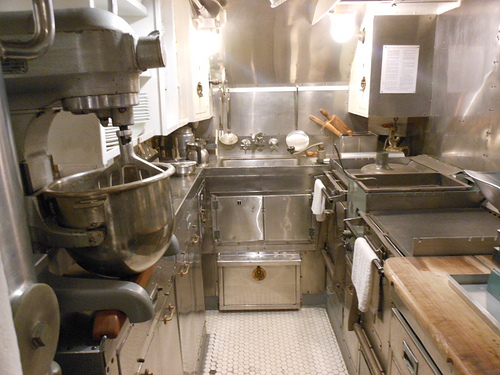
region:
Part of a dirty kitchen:
[197, 163, 332, 324]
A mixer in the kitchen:
[87, 135, 192, 253]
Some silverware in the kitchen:
[250, 104, 395, 179]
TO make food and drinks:
[69, 123, 218, 267]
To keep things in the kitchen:
[168, 158, 350, 253]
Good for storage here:
[166, 155, 361, 266]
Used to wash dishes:
[221, 133, 306, 181]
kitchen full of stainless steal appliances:
[2, 6, 498, 371]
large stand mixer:
[7, 12, 184, 280]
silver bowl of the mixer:
[51, 162, 174, 270]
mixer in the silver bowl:
[94, 124, 164, 190]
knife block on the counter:
[307, 111, 357, 150]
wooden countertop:
[380, 257, 494, 373]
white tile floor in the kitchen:
[198, 299, 353, 374]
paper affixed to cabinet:
[377, 43, 422, 96]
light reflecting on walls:
[190, 7, 360, 92]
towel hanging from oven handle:
[347, 239, 384, 309]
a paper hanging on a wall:
[375, 42, 422, 99]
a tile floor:
[245, 323, 317, 365]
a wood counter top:
[378, 255, 473, 358]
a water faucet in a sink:
[248, 127, 268, 157]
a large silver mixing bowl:
[8, 12, 180, 286]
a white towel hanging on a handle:
[350, 242, 382, 310]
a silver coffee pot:
[184, 135, 205, 172]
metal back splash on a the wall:
[430, 23, 498, 177]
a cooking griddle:
[362, 202, 494, 262]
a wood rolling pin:
[318, 99, 355, 132]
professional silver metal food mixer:
[2, 5, 182, 320]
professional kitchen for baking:
[0, 0, 497, 372]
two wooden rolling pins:
[307, 105, 350, 140]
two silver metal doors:
[210, 189, 319, 244]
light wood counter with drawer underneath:
[383, 255, 498, 374]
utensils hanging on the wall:
[215, 83, 311, 151]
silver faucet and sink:
[211, 130, 301, 169]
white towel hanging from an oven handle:
[342, 214, 386, 319]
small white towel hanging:
[307, 169, 346, 224]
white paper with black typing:
[377, 48, 420, 93]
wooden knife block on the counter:
[310, 107, 348, 140]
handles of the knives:
[308, 109, 333, 130]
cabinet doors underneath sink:
[205, 193, 304, 243]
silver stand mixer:
[4, 37, 184, 325]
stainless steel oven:
[301, 158, 375, 319]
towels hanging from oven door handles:
[308, 179, 387, 316]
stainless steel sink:
[203, 149, 298, 181]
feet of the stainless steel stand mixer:
[50, 220, 179, 322]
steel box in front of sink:
[211, 249, 303, 317]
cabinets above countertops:
[72, 2, 427, 117]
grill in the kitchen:
[363, 205, 498, 256]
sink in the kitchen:
[203, 85, 303, 169]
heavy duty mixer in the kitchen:
[3, 8, 172, 325]